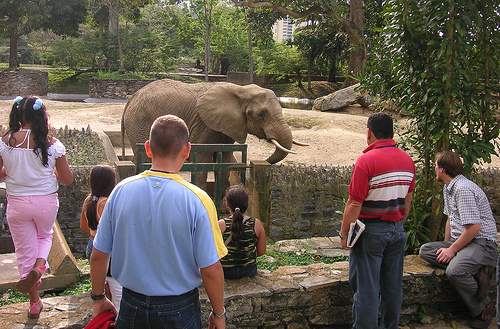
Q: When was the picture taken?
A: Daytime.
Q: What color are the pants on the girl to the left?
A: Pink.